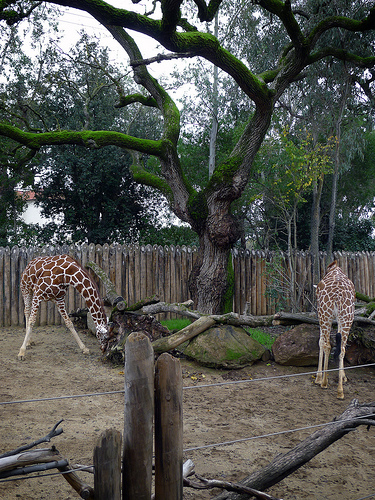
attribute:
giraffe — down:
[310, 227, 356, 403]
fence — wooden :
[3, 244, 367, 324]